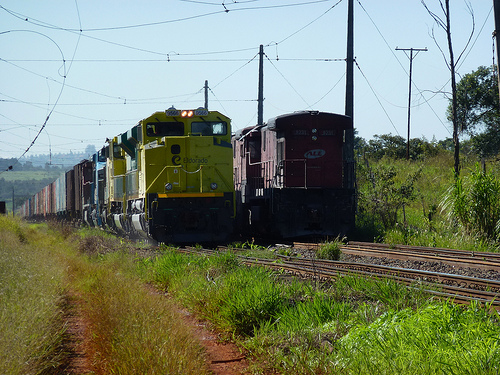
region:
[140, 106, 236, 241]
The front of a train.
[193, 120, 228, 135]
The front window of the train.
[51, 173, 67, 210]
A blue traincar.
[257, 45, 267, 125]
Part of a pole.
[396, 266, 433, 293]
Part of the train tracks.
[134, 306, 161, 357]
Part of the grass.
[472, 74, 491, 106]
Part of a tree.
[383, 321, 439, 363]
Part of the green grass.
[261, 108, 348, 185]
Part of the train.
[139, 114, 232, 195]
Yellowy green front of a train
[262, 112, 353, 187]
Black and red front of a train's front car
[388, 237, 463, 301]
Two rusted metal sets of train tracks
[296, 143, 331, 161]
White logo with red writing on a dark background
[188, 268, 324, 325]
Tufts of thick bright green grass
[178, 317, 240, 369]
Row of red dirt separating two colors of grass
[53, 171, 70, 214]
Blue car of a train behind a darker colored car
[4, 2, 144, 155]
Web of thick black cables stretching across the sky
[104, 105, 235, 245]
Yellow and black train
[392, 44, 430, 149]
Tall lights pole standing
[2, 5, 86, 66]
Electric wires hanging in the air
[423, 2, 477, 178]
A tall leave less tree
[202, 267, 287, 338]
Green wild bushes on the ground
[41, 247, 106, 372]
Walking trail between bushes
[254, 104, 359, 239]
A brown and black train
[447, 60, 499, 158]
A tall green tree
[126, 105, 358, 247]
Two trains side by side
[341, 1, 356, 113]
tall wooden utility pole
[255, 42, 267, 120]
tall wooden utility pole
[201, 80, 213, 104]
tall wooden utility pole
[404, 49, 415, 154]
tall wooden utility pole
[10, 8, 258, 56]
black colored utility wire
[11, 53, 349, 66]
black colored utility wire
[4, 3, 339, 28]
black colored utility wire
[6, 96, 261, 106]
black colored utility wire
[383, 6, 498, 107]
black colored utility wire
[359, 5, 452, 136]
black colored utility wire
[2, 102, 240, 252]
A train on the train tracks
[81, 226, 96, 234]
Part of the grass in distance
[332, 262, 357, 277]
Part of the train tracks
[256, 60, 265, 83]
Part of the power pole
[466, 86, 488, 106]
Part of the tree in distance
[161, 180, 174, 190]
The right headlight of the train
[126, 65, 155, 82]
Part of the blue sky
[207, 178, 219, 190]
The left headlight of the train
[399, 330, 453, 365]
Part of the green bushes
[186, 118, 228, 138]
A window on the train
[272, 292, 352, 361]
the grass is tall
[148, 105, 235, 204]
a train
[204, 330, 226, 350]
the dirt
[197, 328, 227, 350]
the brown dirt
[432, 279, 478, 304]
train tracks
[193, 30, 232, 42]
the clear blue sky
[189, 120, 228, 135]
Window of a train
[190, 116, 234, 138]
Window of a train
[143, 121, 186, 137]
Window of a train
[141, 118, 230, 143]
Windows of a train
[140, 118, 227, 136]
Windows of a train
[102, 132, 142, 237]
A train car on a track.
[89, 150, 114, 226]
A train car on a track.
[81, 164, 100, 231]
A train car on a track.